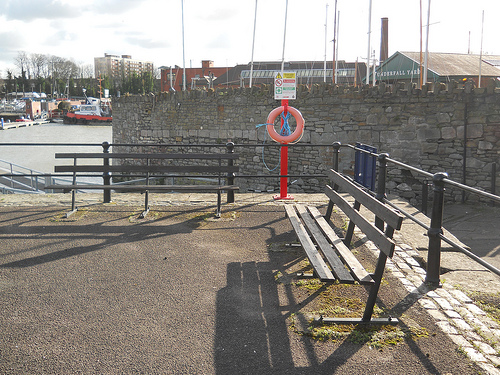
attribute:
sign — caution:
[262, 63, 317, 105]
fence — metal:
[1, 139, 498, 322]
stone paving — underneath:
[3, 192, 498, 372]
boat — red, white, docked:
[62, 103, 110, 122]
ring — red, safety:
[264, 100, 309, 150]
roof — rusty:
[377, 48, 495, 75]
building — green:
[371, 51, 498, 87]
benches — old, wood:
[45, 148, 461, 268]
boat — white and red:
[64, 94, 109, 122]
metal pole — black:
[91, 122, 449, 222]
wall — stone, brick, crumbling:
[110, 88, 498, 207]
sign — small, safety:
[269, 70, 299, 102]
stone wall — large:
[108, 77, 496, 202]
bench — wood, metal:
[295, 160, 403, 304]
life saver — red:
[264, 102, 305, 142]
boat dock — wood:
[7, 79, 49, 137]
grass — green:
[299, 294, 409, 345]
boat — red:
[62, 99, 111, 128]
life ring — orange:
[266, 105, 306, 143]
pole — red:
[281, 99, 288, 199]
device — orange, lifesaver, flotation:
[261, 103, 308, 145]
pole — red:
[270, 152, 298, 188]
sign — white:
[270, 62, 319, 107]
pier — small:
[1, 190, 497, 370]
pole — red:
[276, 96, 289, 198]